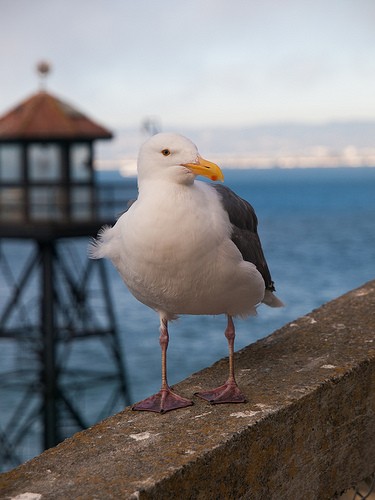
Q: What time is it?
A: Afternoon.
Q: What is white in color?
A: The bird.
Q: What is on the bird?
A: Feathers.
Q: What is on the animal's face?
A: A beak.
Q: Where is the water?
A: Behind the bird.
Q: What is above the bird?
A: The sky.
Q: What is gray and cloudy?
A: The sky.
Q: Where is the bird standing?
A: On a rail.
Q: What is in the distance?
A: A lighthouse.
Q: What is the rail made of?
A: Iron.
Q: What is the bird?
A: Seagull.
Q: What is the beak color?
A: Yellow.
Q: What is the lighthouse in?
A: Water.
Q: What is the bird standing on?
A: A brown wall.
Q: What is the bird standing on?
A: A wall.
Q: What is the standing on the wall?
A: A bird.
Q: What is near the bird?
A: A tower.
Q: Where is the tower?
A: Near water.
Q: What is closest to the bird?
A: The wall.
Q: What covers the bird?
A: Feathers.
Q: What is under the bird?
A: A wall,.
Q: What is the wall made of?
A: Stone.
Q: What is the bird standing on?
A: Legs.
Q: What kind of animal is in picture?
A: Seagull.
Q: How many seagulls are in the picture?
A: One.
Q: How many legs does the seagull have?
A: Two.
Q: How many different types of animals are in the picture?
A: One.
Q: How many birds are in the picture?
A: One.